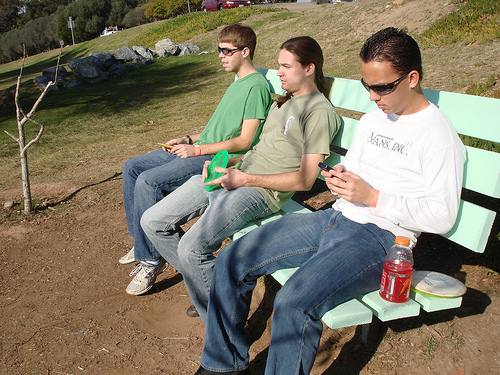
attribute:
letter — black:
[401, 145, 407, 155]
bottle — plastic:
[377, 234, 414, 303]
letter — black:
[378, 137, 387, 148]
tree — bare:
[4, 42, 68, 217]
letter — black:
[369, 132, 379, 143]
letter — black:
[371, 136, 381, 147]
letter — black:
[377, 138, 385, 147]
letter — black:
[383, 140, 391, 150]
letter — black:
[389, 140, 399, 149]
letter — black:
[391, 142, 403, 152]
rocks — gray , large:
[18, 31, 214, 110]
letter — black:
[394, 138, 403, 152]